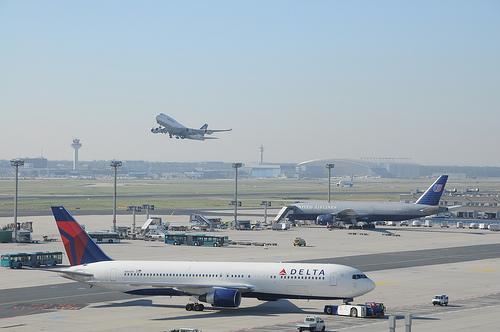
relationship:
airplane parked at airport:
[41, 194, 385, 318] [1, 133, 498, 330]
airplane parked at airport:
[287, 172, 449, 225] [31, 187, 480, 317]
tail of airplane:
[417, 171, 448, 208] [274, 170, 456, 225]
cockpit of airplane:
[349, 272, 372, 285] [42, 204, 375, 308]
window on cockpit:
[352, 274, 356, 279] [349, 272, 372, 285]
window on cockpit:
[356, 273, 359, 278] [349, 272, 372, 285]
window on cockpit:
[360, 274, 363, 278] [349, 272, 372, 285]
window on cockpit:
[363, 274, 368, 277] [349, 272, 372, 285]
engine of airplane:
[196, 287, 241, 307] [48, 194, 385, 326]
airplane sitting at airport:
[284, 174, 448, 229] [3, 171, 498, 329]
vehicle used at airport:
[296, 316, 325, 332] [3, 171, 498, 329]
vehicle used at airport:
[293, 310, 329, 330] [3, 171, 498, 329]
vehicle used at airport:
[28, 251, 65, 267] [1, 133, 498, 330]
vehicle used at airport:
[192, 230, 229, 249] [1, 133, 498, 330]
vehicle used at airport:
[293, 233, 307, 246] [1, 133, 498, 330]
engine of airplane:
[199, 289, 242, 307] [41, 194, 385, 318]